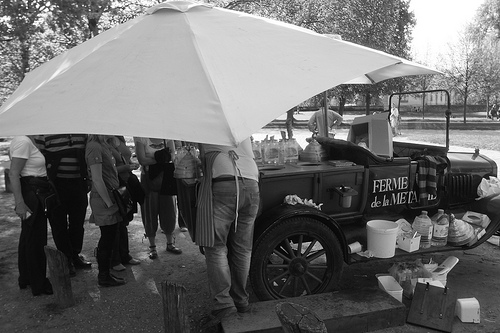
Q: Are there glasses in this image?
A: No, there are no glasses.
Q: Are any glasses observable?
A: No, there are no glasses.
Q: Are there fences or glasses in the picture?
A: No, there are no glasses or fences.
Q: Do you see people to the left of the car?
A: Yes, there are people to the left of the car.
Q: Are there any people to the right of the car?
A: No, the people are to the left of the car.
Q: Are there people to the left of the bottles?
A: Yes, there is a person to the left of the bottles.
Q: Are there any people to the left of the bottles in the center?
A: Yes, there is a person to the left of the bottles.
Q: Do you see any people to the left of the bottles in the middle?
A: Yes, there is a person to the left of the bottles.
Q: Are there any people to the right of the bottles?
A: No, the person is to the left of the bottles.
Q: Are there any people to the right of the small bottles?
A: No, the person is to the left of the bottles.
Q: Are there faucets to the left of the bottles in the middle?
A: No, there is a person to the left of the bottles.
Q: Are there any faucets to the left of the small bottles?
A: No, there is a person to the left of the bottles.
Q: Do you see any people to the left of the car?
A: Yes, there is a person to the left of the car.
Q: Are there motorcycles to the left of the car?
A: No, there is a person to the left of the car.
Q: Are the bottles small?
A: Yes, the bottles are small.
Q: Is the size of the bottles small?
A: Yes, the bottles are small.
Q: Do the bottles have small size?
A: Yes, the bottles are small.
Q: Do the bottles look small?
A: Yes, the bottles are small.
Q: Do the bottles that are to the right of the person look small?
A: Yes, the bottles are small.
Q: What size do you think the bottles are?
A: The bottles are small.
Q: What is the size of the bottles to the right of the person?
A: The bottles are small.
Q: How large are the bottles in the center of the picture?
A: The bottles are small.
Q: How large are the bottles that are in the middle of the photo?
A: The bottles are small.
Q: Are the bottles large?
A: No, the bottles are small.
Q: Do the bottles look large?
A: No, the bottles are small.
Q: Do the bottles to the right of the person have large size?
A: No, the bottles are small.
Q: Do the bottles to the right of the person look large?
A: No, the bottles are small.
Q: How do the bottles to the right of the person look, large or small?
A: The bottles are small.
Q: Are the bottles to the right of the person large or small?
A: The bottles are small.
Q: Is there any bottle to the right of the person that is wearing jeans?
A: Yes, there are bottles to the right of the person.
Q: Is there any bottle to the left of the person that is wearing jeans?
A: No, the bottles are to the right of the person.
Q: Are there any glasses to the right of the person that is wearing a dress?
A: No, there are bottles to the right of the person.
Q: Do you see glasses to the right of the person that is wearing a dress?
A: No, there are bottles to the right of the person.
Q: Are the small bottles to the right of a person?
A: Yes, the bottles are to the right of a person.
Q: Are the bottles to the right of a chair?
A: No, the bottles are to the right of a person.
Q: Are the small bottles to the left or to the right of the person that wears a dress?
A: The bottles are to the right of the person.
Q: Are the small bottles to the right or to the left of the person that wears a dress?
A: The bottles are to the right of the person.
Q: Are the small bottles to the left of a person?
A: No, the bottles are to the right of a person.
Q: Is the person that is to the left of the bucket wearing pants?
A: Yes, the person is wearing pants.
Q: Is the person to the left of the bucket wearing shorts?
A: No, the person is wearing pants.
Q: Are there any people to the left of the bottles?
A: Yes, there is a person to the left of the bottles.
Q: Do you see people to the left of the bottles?
A: Yes, there is a person to the left of the bottles.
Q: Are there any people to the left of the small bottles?
A: Yes, there is a person to the left of the bottles.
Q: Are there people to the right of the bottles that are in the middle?
A: No, the person is to the left of the bottles.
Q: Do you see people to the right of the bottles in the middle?
A: No, the person is to the left of the bottles.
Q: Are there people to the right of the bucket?
A: No, the person is to the left of the bucket.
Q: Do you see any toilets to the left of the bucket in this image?
A: No, there is a person to the left of the bucket.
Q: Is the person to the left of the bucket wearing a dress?
A: Yes, the person is wearing a dress.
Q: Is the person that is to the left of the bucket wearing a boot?
A: No, the person is wearing a dress.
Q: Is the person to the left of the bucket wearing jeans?
A: Yes, the person is wearing jeans.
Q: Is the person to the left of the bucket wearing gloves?
A: No, the person is wearing jeans.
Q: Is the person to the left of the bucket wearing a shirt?
A: Yes, the person is wearing a shirt.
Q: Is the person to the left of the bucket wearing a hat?
A: No, the person is wearing a shirt.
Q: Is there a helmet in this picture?
A: No, there are no helmets.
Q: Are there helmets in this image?
A: No, there are no helmets.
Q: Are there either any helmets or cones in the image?
A: No, there are no helmets or cones.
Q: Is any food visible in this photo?
A: No, there is no food.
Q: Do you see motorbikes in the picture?
A: No, there are no motorbikes.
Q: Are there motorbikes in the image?
A: No, there are no motorbikes.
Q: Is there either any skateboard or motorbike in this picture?
A: No, there are no motorcycles or skateboards.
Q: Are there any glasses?
A: No, there are no glasses.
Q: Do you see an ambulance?
A: No, there are no ambulances.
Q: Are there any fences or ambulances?
A: No, there are no ambulances or fences.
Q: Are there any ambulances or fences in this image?
A: No, there are no ambulances or fences.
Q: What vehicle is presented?
A: The vehicle is a car.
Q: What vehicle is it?
A: The vehicle is a car.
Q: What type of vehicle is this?
A: This is a car.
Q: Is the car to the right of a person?
A: Yes, the car is to the right of a person.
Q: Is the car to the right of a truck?
A: No, the car is to the right of a person.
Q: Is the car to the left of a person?
A: No, the car is to the right of a person.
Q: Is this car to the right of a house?
A: No, the car is to the right of a person.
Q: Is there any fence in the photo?
A: No, there are no fences.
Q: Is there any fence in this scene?
A: No, there are no fences.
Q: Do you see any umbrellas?
A: Yes, there is an umbrella.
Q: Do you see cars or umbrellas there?
A: Yes, there is an umbrella.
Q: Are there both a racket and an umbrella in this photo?
A: No, there is an umbrella but no rackets.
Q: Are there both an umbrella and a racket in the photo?
A: No, there is an umbrella but no rackets.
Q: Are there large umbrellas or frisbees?
A: Yes, there is a large umbrella.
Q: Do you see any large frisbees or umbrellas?
A: Yes, there is a large umbrella.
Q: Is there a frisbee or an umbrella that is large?
A: Yes, the umbrella is large.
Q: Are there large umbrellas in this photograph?
A: Yes, there is a large umbrella.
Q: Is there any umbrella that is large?
A: Yes, there is an umbrella that is large.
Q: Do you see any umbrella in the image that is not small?
A: Yes, there is a large umbrella.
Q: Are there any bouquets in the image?
A: No, there are no bouquets.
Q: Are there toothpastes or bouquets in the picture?
A: No, there are no bouquets or toothpastes.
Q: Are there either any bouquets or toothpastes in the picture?
A: No, there are no bouquets or toothpastes.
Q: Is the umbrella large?
A: Yes, the umbrella is large.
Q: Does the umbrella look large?
A: Yes, the umbrella is large.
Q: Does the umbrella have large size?
A: Yes, the umbrella is large.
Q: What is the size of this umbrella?
A: The umbrella is large.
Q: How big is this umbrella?
A: The umbrella is large.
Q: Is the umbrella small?
A: No, the umbrella is large.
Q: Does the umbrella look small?
A: No, the umbrella is large.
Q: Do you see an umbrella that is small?
A: No, there is an umbrella but it is large.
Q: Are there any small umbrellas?
A: No, there is an umbrella but it is large.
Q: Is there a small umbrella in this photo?
A: No, there is an umbrella but it is large.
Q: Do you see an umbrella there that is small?
A: No, there is an umbrella but it is large.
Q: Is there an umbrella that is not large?
A: No, there is an umbrella but it is large.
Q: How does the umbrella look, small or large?
A: The umbrella is large.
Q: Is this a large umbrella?
A: Yes, this is a large umbrella.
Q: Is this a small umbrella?
A: No, this is a large umbrella.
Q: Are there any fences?
A: No, there are no fences.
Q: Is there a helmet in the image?
A: No, there are no helmets.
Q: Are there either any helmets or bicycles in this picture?
A: No, there are no helmets or bicycles.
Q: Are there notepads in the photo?
A: No, there are no notepads.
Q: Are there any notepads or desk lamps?
A: No, there are no notepads or desk lamps.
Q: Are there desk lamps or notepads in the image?
A: No, there are no notepads or desk lamps.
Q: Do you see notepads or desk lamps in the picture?
A: No, there are no notepads or desk lamps.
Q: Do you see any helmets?
A: No, there are no helmets.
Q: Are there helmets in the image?
A: No, there are no helmets.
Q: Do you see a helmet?
A: No, there are no helmets.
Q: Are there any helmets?
A: No, there are no helmets.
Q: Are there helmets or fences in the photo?
A: No, there are no helmets or fences.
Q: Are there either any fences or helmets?
A: No, there are no helmets or fences.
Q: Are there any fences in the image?
A: No, there are no fences.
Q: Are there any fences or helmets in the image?
A: No, there are no fences or helmets.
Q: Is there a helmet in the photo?
A: No, there are no helmets.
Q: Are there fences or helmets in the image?
A: No, there are no helmets or fences.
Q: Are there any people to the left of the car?
A: Yes, there is a person to the left of the car.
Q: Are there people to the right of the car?
A: No, the person is to the left of the car.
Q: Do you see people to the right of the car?
A: No, the person is to the left of the car.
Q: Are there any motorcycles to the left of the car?
A: No, there is a person to the left of the car.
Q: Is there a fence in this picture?
A: No, there are no fences.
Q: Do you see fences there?
A: No, there are no fences.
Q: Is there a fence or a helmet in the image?
A: No, there are no fences or helmets.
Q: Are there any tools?
A: No, there are no tools.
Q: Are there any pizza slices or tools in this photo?
A: No, there are no tools or pizza slices.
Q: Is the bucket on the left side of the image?
A: No, the bucket is on the right of the image.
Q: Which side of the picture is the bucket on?
A: The bucket is on the right of the image.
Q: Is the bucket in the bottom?
A: Yes, the bucket is in the bottom of the image.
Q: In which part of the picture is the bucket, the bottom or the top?
A: The bucket is in the bottom of the image.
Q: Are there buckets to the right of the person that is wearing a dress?
A: Yes, there is a bucket to the right of the person.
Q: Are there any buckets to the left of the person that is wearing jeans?
A: No, the bucket is to the right of the person.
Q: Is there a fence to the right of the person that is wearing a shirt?
A: No, there is a bucket to the right of the person.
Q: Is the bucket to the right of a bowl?
A: No, the bucket is to the right of the person.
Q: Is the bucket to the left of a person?
A: No, the bucket is to the right of a person.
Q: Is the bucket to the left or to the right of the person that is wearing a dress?
A: The bucket is to the right of the person.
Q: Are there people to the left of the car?
A: Yes, there is a person to the left of the car.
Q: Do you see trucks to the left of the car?
A: No, there is a person to the left of the car.